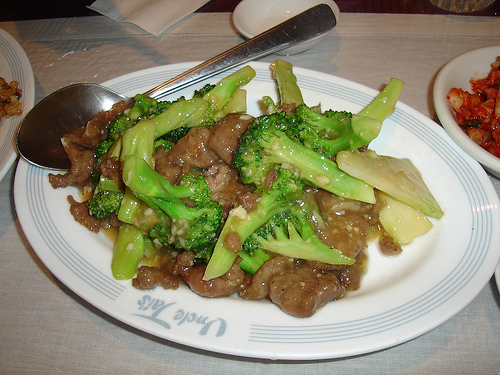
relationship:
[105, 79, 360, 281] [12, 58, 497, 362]
food in plate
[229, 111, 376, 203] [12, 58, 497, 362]
broccoli on plate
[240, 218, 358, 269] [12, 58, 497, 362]
broccoli on plate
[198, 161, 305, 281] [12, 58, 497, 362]
broccoli on plate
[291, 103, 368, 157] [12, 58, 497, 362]
broccoli on plate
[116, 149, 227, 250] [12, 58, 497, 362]
broccoli on plate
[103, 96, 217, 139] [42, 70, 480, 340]
broccoli on plate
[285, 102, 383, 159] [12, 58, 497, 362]
broccoli on plate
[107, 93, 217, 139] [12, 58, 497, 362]
broccoli on plate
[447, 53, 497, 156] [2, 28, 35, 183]
food on plate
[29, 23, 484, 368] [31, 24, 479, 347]
plate on table